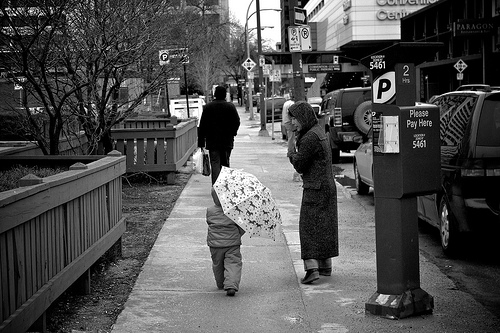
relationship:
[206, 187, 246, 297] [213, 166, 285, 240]
child has umbrella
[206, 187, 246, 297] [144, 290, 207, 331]
child on sidewalk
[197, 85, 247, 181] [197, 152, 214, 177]
man has bag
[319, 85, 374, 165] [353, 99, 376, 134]
vehicle has tire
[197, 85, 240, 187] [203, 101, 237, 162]
man wears clothing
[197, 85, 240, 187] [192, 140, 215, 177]
man carries bag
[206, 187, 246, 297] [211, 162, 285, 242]
child carries umbrella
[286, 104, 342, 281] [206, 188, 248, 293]
mother with child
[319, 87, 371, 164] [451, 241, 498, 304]
vehicle on road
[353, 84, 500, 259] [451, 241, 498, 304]
cars on road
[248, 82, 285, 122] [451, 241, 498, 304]
vehicles on road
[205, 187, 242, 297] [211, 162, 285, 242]
child holds umbrella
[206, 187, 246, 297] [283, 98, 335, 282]
child with woman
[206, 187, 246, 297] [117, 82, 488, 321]
child on sidewalk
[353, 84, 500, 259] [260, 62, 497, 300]
cars on street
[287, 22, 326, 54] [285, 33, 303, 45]
sign with arrow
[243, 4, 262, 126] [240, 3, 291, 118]
light on curved pole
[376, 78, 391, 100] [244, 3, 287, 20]
letter on white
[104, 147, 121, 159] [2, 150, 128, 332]
post on fence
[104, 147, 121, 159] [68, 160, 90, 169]
post on post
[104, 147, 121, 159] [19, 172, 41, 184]
post on post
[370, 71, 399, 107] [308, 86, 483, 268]
sign on street